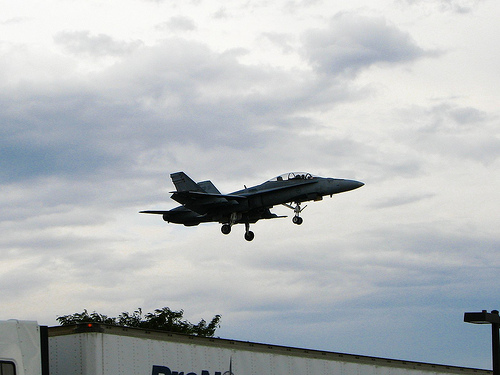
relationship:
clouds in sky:
[2, 1, 499, 373] [2, 0, 499, 368]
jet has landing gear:
[139, 170, 365, 241] [292, 201, 303, 225]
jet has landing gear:
[139, 170, 365, 241] [243, 221, 255, 239]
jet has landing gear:
[139, 170, 365, 241] [222, 214, 236, 234]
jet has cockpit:
[139, 170, 365, 241] [271, 171, 313, 180]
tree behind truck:
[58, 305, 220, 337] [1, 320, 499, 374]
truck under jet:
[1, 320, 499, 374] [139, 170, 365, 241]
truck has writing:
[1, 320, 499, 374] [152, 365, 231, 374]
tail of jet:
[139, 173, 221, 225] [139, 170, 365, 241]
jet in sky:
[139, 170, 365, 241] [2, 0, 499, 368]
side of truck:
[98, 326, 493, 374] [1, 320, 499, 374]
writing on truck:
[152, 365, 231, 374] [1, 320, 499, 374]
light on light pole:
[462, 310, 498, 324] [492, 309, 500, 372]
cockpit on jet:
[271, 171, 313, 180] [139, 170, 365, 241]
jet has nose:
[139, 170, 365, 241] [315, 176, 365, 198]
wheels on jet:
[292, 217, 302, 224] [139, 170, 365, 241]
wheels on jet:
[292, 217, 302, 224] [245, 232, 253, 240]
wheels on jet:
[222, 226, 231, 234] [139, 170, 365, 241]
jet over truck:
[139, 170, 365, 241] [1, 320, 499, 374]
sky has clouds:
[2, 0, 499, 368] [2, 1, 499, 373]